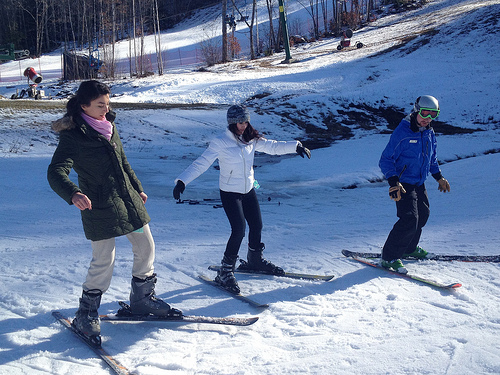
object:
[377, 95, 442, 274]
man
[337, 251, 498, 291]
skiis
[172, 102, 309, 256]
girl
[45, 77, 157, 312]
woman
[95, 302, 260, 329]
ski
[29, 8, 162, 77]
tree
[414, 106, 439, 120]
googles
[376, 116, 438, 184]
jacket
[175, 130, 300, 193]
jacket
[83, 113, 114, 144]
scarf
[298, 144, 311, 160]
glove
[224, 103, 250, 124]
hat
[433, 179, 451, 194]
gloves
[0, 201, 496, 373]
track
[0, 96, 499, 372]
snow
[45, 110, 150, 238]
coat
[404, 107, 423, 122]
hhod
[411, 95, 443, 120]
helmet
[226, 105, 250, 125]
cap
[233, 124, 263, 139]
hair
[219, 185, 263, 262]
pants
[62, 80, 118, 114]
head